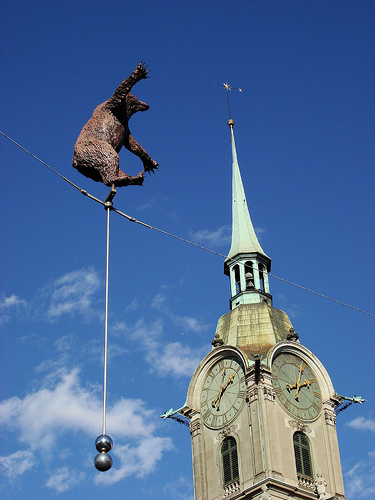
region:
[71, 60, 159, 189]
bear statue on top of wire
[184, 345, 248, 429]
clock face on the side of a tower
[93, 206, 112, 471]
two silver metal balls on the end of a rod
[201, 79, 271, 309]
pointed top of a clock tower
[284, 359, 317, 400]
golden colored hands on the clock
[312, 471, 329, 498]
small stone statue on the building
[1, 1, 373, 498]
white clouds in blue sky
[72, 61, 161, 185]
bear statue in mid air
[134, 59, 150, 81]
bear paw of statue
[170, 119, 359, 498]
corner of clock tower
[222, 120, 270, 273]
steeple on clock tower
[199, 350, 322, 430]
two round clock faces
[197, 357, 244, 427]
roman numerals on clock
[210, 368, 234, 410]
two hands on clock face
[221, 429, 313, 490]
two windows with arched tops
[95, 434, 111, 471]
two shiny silver balls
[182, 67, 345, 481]
This is a clock tower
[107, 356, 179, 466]
section of the clouds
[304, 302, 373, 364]
section of the clouds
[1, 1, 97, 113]
section of the clouds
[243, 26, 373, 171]
section of the clouds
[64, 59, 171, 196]
statue of a bear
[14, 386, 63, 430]
the clouds are white in the sky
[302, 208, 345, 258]
a clear blue sky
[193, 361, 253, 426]
a clock on the building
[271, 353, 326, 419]
the clock on the side of the building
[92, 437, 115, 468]
two balls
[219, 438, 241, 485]
a window on the building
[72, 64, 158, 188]
statute of a bear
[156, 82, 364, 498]
clock tower with steeple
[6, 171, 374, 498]
wispy clouds in the sky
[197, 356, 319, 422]
light blue faces of the clocks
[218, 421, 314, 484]
windows on the clock tower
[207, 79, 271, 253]
steeple of the clock tower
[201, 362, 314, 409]
gold hands on the clocks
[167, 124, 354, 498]
gray and light blue clock tower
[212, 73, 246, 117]
cross on the top of the clock tower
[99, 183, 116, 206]
base of the bear statute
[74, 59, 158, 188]
a brown bear statue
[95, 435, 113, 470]
two large metal balls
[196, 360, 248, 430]
a clock on the side of a building